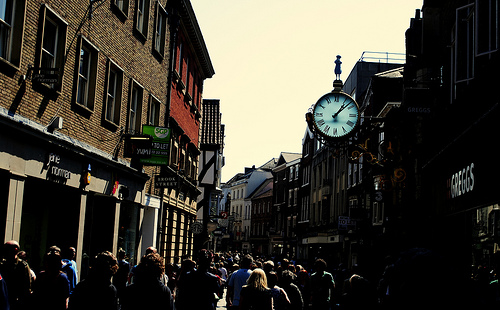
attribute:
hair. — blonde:
[244, 262, 271, 297]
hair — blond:
[246, 267, 270, 289]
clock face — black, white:
[311, 89, 360, 139]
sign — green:
[135, 122, 175, 167]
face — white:
[315, 95, 357, 132]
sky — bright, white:
[192, 4, 416, 186]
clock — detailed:
[305, 53, 370, 150]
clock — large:
[312, 93, 359, 139]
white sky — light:
[188, 0, 413, 183]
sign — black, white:
[157, 172, 179, 187]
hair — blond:
[245, 263, 274, 294]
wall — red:
[163, 25, 203, 184]